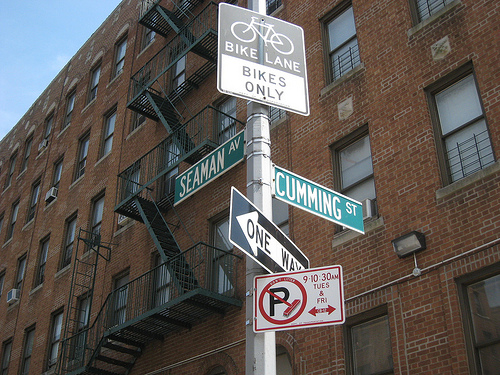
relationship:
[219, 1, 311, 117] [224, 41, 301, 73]
sign says bike lane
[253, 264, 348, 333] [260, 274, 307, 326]
sign says no parking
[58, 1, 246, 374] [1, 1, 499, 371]
fire escape on building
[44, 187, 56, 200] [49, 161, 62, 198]
air conditioner in window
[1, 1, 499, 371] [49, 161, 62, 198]
building has a window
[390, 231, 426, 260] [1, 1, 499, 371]
light on building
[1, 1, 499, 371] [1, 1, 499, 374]
building has windows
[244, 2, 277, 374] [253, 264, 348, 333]
pole with sign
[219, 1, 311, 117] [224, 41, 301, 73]
sign for bike lane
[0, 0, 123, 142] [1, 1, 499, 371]
sky over building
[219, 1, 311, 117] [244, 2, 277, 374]
sign on pole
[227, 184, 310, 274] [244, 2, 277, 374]
sign on pole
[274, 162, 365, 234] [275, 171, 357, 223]
sign says cumming st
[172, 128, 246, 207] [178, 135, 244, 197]
sign says seaman av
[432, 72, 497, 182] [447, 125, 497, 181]
window with bars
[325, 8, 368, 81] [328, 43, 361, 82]
window with bars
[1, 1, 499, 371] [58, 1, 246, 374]
building has a fire escape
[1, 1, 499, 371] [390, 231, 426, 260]
building has a light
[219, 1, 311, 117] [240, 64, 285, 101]
sign for bikes only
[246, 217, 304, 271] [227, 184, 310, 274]
one way on sign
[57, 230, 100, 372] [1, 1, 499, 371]
ladder on building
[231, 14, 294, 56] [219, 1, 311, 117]
bike on sign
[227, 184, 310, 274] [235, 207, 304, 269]
sign has a arrow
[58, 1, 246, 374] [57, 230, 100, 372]
fire escape has a ladder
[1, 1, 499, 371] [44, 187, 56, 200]
building has a air conditioner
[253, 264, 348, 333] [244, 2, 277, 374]
sign on pole